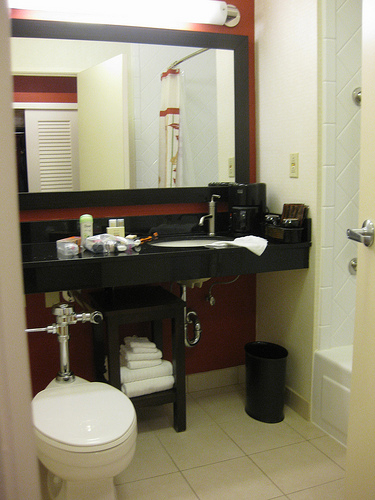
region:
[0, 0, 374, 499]
A bathroom with a large mirror.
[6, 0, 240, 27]
An oblong light fixture with a white cover.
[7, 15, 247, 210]
A large mirror with a black frame.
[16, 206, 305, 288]
A long black countertop.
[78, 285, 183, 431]
Small dark brown shelf under the countertop.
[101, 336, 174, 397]
Folded white towels and cloths on the shelf.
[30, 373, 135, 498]
White toilet bowl with the lid down.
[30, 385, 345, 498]
Tan floor tiles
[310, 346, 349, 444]
The edge of a white bathtub.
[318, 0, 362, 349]
White tile on the wall above the bathtub.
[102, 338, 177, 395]
Six white towels stacked on top of each other.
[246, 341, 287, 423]
Black trash bin in bathroom.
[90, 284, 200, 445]
Small black stool under sink counter.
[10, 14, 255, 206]
Black framed mirror on bathroom wall.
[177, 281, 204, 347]
Metal sink pipe under counter.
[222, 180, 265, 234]
Small black coffee maker in corner.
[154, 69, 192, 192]
Reflection of shower curtain in bathroom mirror.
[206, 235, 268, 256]
Small white towel hanging over sink.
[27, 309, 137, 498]
White and metal toilet with lid down.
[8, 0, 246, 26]
Long white and metal light hang over bathroom mirror.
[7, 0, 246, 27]
light at top of mirror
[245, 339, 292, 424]
black trash can on floor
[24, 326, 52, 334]
silver handle on toilet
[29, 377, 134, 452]
toilet seat on the toilet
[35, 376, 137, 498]
white toilet in the bathroom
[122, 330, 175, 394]
white towels on shelf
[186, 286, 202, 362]
silver pipe under the sink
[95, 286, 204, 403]
black stool in bathroom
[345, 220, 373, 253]
silver handle on door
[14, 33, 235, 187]
mirror in the room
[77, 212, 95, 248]
stick of dove deodorant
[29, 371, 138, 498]
white porcelain commode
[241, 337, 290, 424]
small black trash can without a trash bag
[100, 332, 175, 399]
stack of white towels and wash rags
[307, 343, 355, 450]
corner of a white bath tub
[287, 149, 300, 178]
outlet for miniature coffee pot and hair dryer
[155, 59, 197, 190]
double shower curtain for the shower/bath tub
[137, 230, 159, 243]
orange and black toothbrush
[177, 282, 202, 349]
stainless steel plumbing underneath the sink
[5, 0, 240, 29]
large incandescent light over the sink and counter